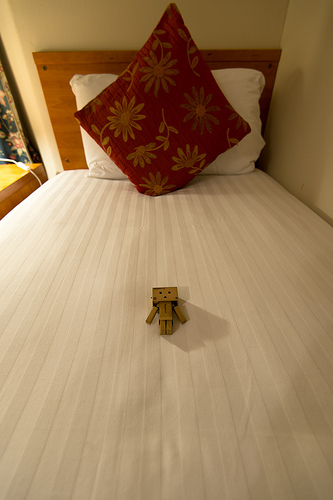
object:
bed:
[2, 48, 331, 497]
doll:
[145, 282, 186, 335]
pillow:
[73, 4, 253, 198]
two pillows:
[65, 4, 268, 197]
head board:
[30, 44, 282, 176]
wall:
[2, 1, 333, 225]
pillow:
[68, 64, 268, 181]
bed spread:
[0, 168, 333, 499]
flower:
[179, 85, 219, 136]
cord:
[1, 157, 43, 187]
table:
[1, 157, 46, 219]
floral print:
[6, 130, 27, 155]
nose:
[164, 295, 167, 298]